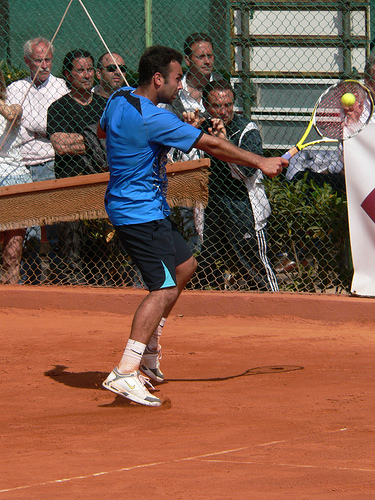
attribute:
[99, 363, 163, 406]
foot — man's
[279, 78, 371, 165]
racquet — in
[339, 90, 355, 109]
ball — green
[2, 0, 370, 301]
fence — metal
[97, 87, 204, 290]
tennis clothes — Blue , black 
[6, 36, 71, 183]
spectator — behind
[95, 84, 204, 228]
shirt — blue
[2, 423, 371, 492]
white line — in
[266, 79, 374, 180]
racket — yellow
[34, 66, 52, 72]
man — older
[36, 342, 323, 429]
shadow — on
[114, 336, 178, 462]
shoes — are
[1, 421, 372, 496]
line — white, fading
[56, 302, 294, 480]
court — brown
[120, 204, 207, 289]
shorts — are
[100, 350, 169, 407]
shoes — white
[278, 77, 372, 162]
racket — is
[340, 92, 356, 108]
ball — tennis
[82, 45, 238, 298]
man — tennis player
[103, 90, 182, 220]
blue shirt — short-sleeved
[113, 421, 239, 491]
clay — red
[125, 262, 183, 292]
shorts — on